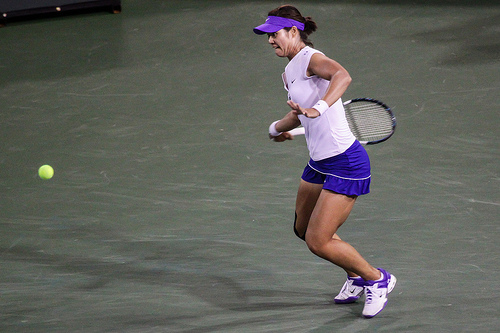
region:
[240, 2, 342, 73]
She is wearing a purple visor.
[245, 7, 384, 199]
She is wearing a white shirt.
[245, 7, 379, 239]
She is wearing a blue skirt.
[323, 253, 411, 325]
She is wearing white shoes.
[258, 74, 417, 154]
She is swinging the racket.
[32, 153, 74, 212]
The ball is yellow.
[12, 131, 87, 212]
The ball is moving.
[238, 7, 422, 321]
She is playing tennis.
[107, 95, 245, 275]
The ground is grey.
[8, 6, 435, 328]
She is hitting the tennis ball.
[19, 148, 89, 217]
tennis ball in the air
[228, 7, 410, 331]
woman playing tennis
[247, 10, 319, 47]
purple tennis visor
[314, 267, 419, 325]
white and purple tennis shoes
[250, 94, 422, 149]
white and blue tennis racket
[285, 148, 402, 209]
blue tennis skirt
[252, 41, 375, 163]
white Nike tennis shirt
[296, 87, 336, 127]
sweat bands on her wrist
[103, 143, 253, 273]
scuff marks on the court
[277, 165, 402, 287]
her knees are bent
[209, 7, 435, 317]
The tennis player is focusing on the ball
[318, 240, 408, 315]
She is wearing tennis shoes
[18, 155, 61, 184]
The tennis ball is in the air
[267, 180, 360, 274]
The woman is bending her knees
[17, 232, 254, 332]
Shadow on the court from woman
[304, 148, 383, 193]
Short tennis skirt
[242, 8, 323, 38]
The woman is wearing a purple visor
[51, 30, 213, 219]
The tennis court floor is scratched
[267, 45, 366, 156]
Tennis player wearing a Nike polo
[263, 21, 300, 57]
The woman's face looks determined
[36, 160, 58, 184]
the ball is green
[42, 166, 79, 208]
the ball is green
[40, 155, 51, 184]
the ball is green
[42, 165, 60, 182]
the ball is green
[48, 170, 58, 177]
the ball is green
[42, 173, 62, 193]
the ball is green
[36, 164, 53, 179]
green ball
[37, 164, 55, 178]
green tennis ball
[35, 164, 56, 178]
ball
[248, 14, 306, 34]
purple visor on the tennis player's head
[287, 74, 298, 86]
nike logo on the woman's shirt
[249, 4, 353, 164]
player wearing a light purple shirt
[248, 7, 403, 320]
female tennis player dressed in purple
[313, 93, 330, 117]
white band on the woman's wrist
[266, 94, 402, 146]
white and black tennis racket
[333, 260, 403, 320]
purple and white Nikes